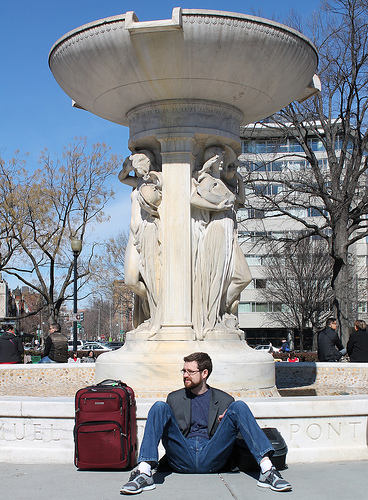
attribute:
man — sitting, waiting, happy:
[149, 364, 252, 465]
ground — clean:
[34, 464, 69, 499]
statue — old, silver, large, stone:
[86, 40, 273, 326]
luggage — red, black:
[76, 374, 133, 462]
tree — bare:
[275, 140, 341, 217]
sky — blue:
[4, 32, 46, 108]